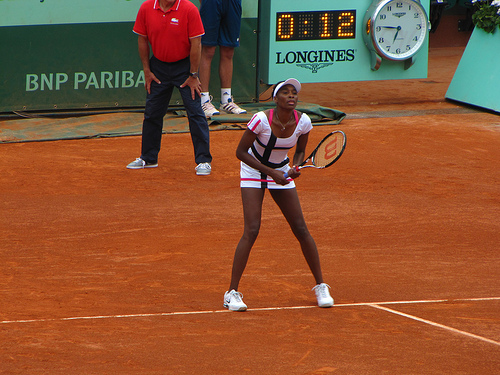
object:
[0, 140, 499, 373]
court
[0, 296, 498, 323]
lines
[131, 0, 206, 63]
shirt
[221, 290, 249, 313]
shoes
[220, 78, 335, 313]
venus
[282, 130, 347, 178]
racket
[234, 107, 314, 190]
outfit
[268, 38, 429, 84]
advert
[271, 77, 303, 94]
visor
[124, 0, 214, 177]
line judge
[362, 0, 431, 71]
clock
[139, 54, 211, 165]
pants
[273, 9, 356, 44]
time